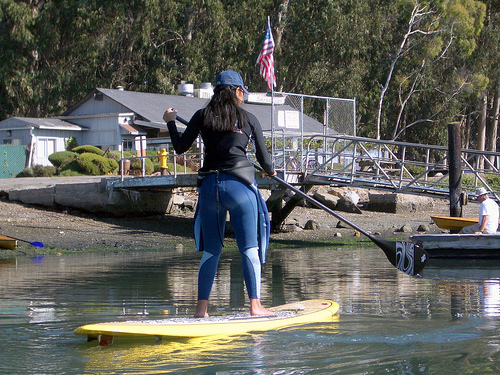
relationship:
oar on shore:
[29, 240, 49, 249] [4, 198, 194, 275]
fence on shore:
[268, 77, 356, 165] [46, 187, 175, 286]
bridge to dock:
[262, 131, 499, 206] [0, 176, 479, 256]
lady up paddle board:
[162, 70, 277, 319] [79, 299, 341, 343]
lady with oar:
[162, 70, 277, 319] [163, 107, 427, 277]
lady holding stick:
[162, 70, 277, 319] [165, 106, 430, 278]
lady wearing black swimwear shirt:
[162, 70, 277, 319] [168, 94, 292, 186]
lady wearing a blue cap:
[162, 70, 277, 319] [211, 69, 249, 95]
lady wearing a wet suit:
[162, 70, 277, 319] [186, 169, 275, 304]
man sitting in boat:
[455, 181, 497, 239] [444, 209, 498, 300]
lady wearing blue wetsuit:
[163, 53, 290, 323] [197, 173, 260, 300]